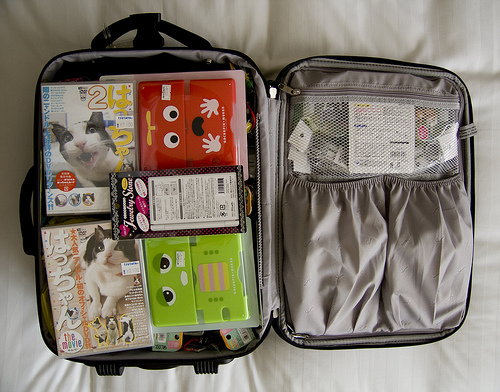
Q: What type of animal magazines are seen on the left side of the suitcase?
A: Cats.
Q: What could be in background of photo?
A: Mattress.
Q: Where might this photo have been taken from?
A: Above bed.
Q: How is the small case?
A: Open.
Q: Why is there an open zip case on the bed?
A: To pack DVD movies.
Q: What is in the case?
A: DVD movies.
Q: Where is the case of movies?
A: On the bed.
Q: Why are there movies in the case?
A: To take on a trip.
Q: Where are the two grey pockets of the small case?
A: The inside top of case.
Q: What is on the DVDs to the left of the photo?
A: Cats.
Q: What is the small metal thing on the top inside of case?
A: A zipper.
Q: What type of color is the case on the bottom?
A: Green.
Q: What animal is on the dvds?
A: Cats.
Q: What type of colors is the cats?
A: Black and white.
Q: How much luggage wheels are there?
A: 2.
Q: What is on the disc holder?
A: Silly face.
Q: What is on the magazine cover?
A: Cat.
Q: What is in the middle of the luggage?
A: Cards.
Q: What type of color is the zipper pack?
A: Gray.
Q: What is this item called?
A: A zipper pack.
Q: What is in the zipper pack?
A: Assorted objects.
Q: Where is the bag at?
A: On a bed.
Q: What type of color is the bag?
A: Black.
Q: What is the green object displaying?
A: A face.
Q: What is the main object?
A: Carrying case.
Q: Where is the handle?
A: Left side.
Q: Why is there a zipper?
A: To secure items.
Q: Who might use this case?
A: Traveler.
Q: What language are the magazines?
A: Chinese.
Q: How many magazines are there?
A: Two.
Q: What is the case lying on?
A: A bed.